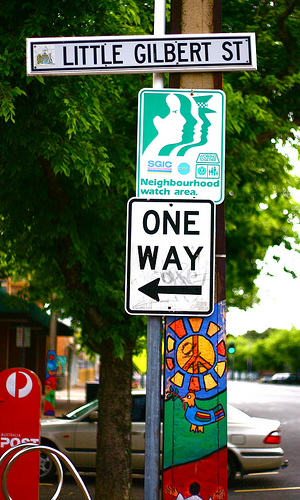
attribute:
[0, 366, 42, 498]
sign — street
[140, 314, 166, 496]
pole — grey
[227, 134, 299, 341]
sky — clear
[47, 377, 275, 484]
car — beige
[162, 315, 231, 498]
pole — Hand-painted, decorated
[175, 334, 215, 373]
sign — Peace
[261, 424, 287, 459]
light — tail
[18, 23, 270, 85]
sign — street sign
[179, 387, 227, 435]
bird — Hand-painted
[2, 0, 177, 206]
trees — green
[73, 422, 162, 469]
door — tan, driver's, driver's-side, side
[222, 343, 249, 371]
light — green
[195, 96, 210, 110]
brim — Checkered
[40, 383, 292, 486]
car — tan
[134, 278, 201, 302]
arrow — black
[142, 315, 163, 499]
post — metal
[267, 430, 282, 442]
light — red rear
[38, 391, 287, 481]
car — Gold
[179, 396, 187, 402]
mouth — bird's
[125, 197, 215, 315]
sign — black, white, one way